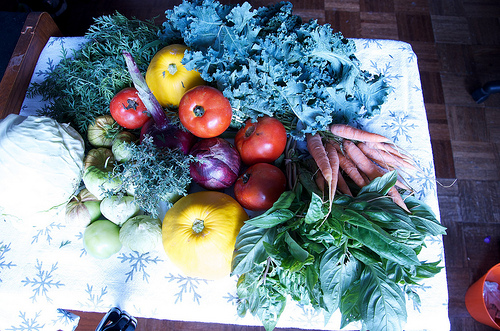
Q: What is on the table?
A: Fruits.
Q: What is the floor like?
A: Tiled.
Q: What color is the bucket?
A: Orange.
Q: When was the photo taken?
A: Daytime.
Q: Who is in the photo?
A: Nobody.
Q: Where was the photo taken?
A: This photo was taken in a kitchen.